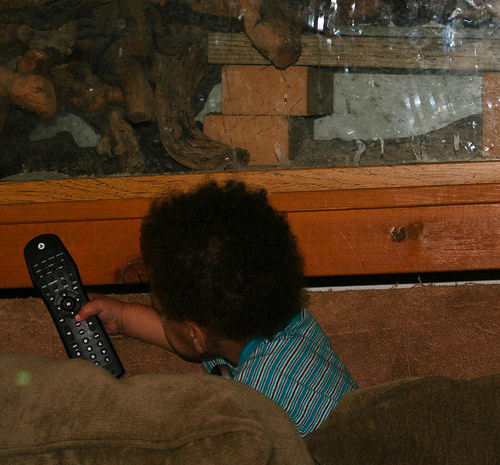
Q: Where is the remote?
A: In the toddler's hand.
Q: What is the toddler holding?
A: A remote.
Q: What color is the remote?
A: Black.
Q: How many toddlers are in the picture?
A: One.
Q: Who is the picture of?
A: A toddler.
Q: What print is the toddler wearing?
A: Stripes.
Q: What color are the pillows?
A: Brown.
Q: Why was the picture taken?
A: To capture the toddler.